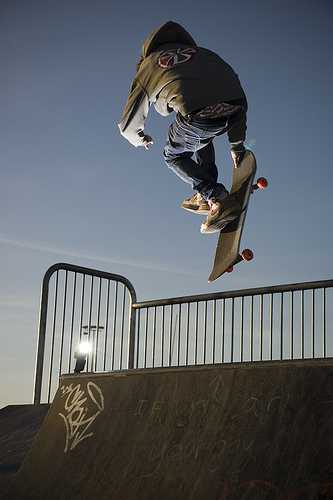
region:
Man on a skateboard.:
[119, 24, 280, 313]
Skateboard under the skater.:
[186, 99, 281, 322]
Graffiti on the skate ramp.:
[38, 358, 120, 450]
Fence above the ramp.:
[58, 253, 265, 405]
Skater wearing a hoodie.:
[98, 23, 249, 135]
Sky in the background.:
[31, 142, 252, 369]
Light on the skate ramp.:
[56, 314, 115, 379]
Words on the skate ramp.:
[141, 388, 286, 473]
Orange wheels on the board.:
[244, 156, 285, 221]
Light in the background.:
[74, 298, 119, 376]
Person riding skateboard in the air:
[123, 30, 270, 272]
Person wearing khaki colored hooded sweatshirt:
[120, 23, 253, 116]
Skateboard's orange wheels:
[213, 244, 255, 273]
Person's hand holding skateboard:
[216, 135, 262, 178]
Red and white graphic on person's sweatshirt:
[154, 46, 207, 75]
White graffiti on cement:
[50, 375, 108, 451]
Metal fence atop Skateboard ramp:
[119, 286, 332, 381]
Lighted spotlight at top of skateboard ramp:
[64, 336, 105, 381]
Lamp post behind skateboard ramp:
[81, 319, 113, 369]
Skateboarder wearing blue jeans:
[159, 119, 257, 212]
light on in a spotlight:
[73, 331, 92, 362]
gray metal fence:
[36, 261, 330, 396]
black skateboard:
[210, 148, 258, 280]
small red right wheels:
[242, 165, 266, 260]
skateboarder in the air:
[111, 18, 252, 223]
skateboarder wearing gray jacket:
[115, 22, 249, 227]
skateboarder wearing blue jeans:
[118, 19, 261, 232]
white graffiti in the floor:
[52, 381, 104, 452]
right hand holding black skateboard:
[205, 45, 247, 165]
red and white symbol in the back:
[155, 44, 195, 73]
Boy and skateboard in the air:
[86, 32, 286, 290]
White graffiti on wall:
[47, 372, 115, 477]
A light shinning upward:
[61, 334, 102, 379]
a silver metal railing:
[33, 247, 332, 388]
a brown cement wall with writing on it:
[14, 371, 332, 496]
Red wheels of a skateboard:
[237, 176, 270, 267]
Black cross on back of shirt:
[144, 43, 209, 75]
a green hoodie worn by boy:
[110, 18, 264, 145]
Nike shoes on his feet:
[180, 189, 246, 235]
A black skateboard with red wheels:
[210, 152, 263, 288]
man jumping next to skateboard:
[110, 15, 268, 258]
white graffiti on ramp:
[55, 372, 116, 455]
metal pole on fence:
[215, 281, 272, 306]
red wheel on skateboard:
[250, 168, 273, 196]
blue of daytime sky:
[281, 56, 327, 110]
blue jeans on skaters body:
[162, 104, 248, 204]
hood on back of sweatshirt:
[143, 13, 210, 64]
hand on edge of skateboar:
[226, 137, 254, 172]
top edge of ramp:
[206, 354, 280, 404]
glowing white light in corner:
[67, 329, 97, 382]